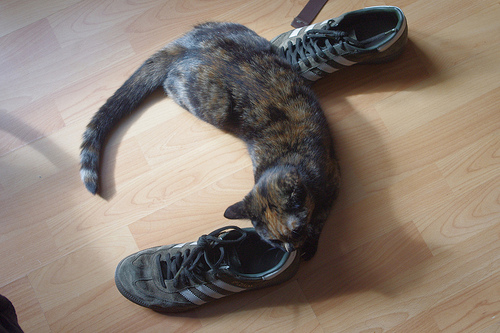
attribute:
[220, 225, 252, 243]
shoe string — gray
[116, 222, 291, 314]
sneaker — grey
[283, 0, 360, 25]
strap — purple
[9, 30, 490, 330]
floor — wood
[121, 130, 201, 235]
shades — brown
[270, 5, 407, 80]
shoe — black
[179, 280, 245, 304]
stripes — white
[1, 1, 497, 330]
floor — wood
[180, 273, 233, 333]
stripes — white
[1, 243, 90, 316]
pattern — wood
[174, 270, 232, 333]
strpes — white